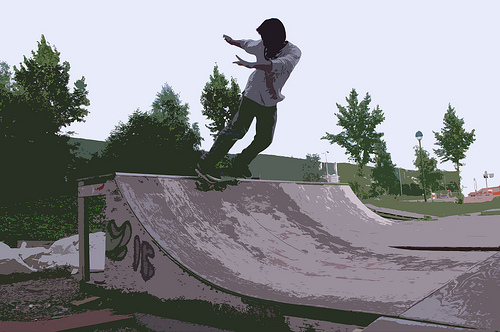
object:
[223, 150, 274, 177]
shoe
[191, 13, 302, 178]
man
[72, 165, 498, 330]
ramp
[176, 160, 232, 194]
right shoe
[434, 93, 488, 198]
tree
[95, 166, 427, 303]
horse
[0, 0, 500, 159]
cloud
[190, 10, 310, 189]
skater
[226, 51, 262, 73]
hand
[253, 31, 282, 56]
face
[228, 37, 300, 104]
shirt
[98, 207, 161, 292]
graffiti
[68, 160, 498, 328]
skateboard ramp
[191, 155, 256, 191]
skateboard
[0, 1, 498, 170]
blue sky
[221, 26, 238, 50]
hand